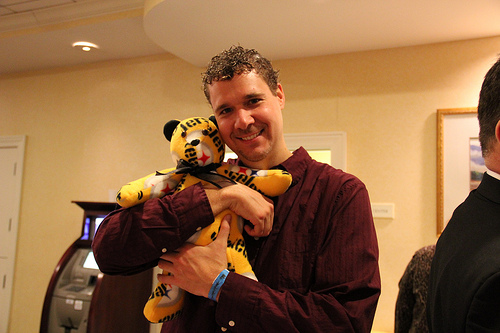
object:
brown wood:
[435, 106, 447, 239]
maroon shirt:
[93, 144, 382, 332]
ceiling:
[0, 0, 499, 79]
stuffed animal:
[113, 113, 293, 324]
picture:
[432, 106, 484, 236]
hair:
[200, 44, 281, 111]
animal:
[115, 114, 292, 323]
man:
[424, 51, 500, 332]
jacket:
[423, 169, 500, 333]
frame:
[434, 105, 494, 238]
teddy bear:
[118, 114, 292, 323]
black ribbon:
[155, 158, 237, 188]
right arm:
[90, 180, 233, 276]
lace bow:
[155, 159, 237, 189]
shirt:
[89, 146, 381, 333]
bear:
[115, 114, 293, 325]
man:
[93, 45, 380, 331]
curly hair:
[201, 41, 281, 108]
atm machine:
[38, 201, 134, 333]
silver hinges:
[0, 161, 19, 290]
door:
[1, 134, 28, 332]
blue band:
[208, 268, 230, 303]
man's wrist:
[206, 264, 246, 310]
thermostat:
[370, 202, 395, 220]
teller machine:
[40, 199, 121, 332]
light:
[72, 40, 99, 51]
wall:
[0, 35, 499, 333]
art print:
[437, 107, 485, 239]